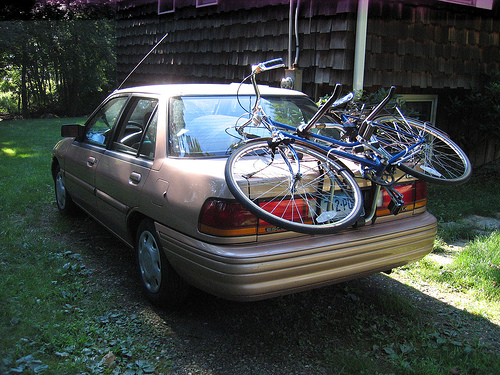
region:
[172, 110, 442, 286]
blue and silver bike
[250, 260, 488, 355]
shady area on ground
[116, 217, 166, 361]
black tire with silver rim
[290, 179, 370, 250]
white license plate with blue letters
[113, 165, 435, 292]
red tail lights of a car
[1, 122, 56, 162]
sun lit patch in grassy area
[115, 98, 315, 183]
rear view window of acar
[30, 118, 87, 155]
side mirror on a car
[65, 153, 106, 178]
tan door handle of car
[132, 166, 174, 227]
dorr for a gas tank on car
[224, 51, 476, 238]
a blue bike on the car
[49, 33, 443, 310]
a small tan car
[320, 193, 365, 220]
a blue and white license plate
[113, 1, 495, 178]
a brown wooden sided building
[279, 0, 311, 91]
a utility meter on the building side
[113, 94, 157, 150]
an open car window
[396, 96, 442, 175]
a window on the building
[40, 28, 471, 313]
a car hauling a blue bike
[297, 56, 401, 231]
a car bike rack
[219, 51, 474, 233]
a bike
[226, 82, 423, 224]
a blue bicycle on a car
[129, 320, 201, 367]
gravel under the car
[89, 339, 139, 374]
a small patch of green ivy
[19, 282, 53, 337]
grass growing near the path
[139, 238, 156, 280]
a silver hubcap on the car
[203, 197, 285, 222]
the red taillights on the car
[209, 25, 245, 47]
brown wooden shutters on a house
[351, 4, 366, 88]
a white drain pipe on the side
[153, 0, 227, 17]
windows on the side of the house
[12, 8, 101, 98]
a thicket of small green trees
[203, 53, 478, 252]
Bike strapped to the back of a car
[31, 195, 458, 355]
Missing grass due to heavy parking in this area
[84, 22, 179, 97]
Car antenna extending from the front windshield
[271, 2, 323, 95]
Electric meter on the side of the house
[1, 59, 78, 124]
Meadow just past the trees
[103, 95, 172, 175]
Back window rolled down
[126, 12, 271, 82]
Old roof style siding on the house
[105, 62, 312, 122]
Sun hitting the top of the car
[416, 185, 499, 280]
Sidewalk with grass growing in the cracks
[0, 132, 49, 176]
Sunlight shining through the trees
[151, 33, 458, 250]
a bike tied to the trunk of a car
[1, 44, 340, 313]
a four door car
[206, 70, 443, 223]
a blue bike tied to a car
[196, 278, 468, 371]
a gravel driveway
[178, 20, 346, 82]
a wood shingled house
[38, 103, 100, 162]
a rear view mirror on a car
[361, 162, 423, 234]
two foot peddles on a bike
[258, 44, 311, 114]
a electric meter on the side of a house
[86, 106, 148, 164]
steering wheel of a car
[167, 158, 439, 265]
red and yellow tail lights on a car